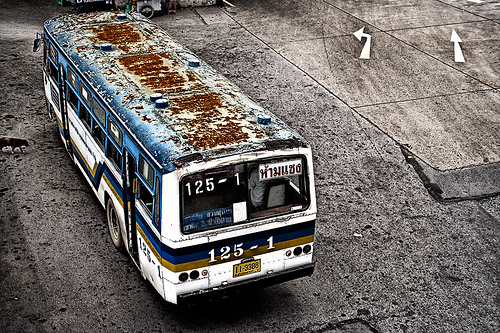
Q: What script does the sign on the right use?
A: Thai.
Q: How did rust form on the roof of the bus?
A: Heavy rains coupled with poor maintenance.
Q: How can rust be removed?
A: Through specialized chemicals.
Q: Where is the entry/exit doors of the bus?
A: On the driver's side, behind each wheel.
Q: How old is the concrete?
A: 50 years.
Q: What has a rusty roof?
A: The bus.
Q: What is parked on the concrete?
A: The bus.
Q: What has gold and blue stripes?
A: The bus.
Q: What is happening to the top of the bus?
A: It is rusted.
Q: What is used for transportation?
A: The bus.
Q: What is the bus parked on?
A: A road.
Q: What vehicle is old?
A: The bus.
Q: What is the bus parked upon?
A: Gray concrete.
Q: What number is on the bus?
A: 125-1.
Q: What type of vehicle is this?
A: A bus.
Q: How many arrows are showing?
A: Two.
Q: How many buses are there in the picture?
A: One.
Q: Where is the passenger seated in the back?
A: Right.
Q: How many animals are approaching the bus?
A: One.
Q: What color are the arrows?
A: White.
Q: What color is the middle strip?
A: Blue.